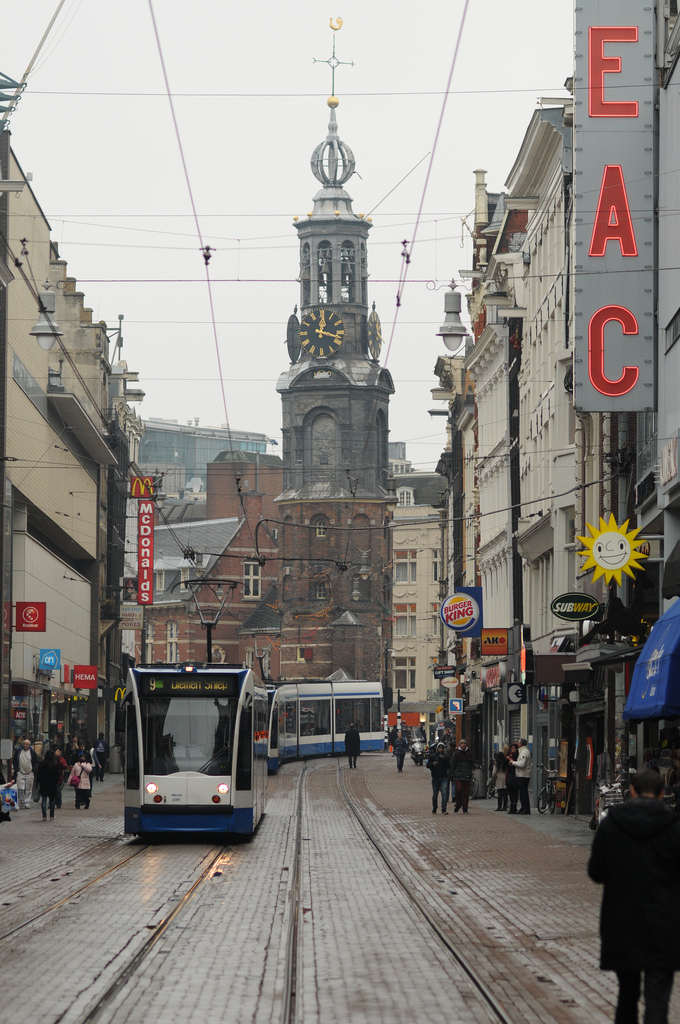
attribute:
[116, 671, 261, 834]
train — blue, white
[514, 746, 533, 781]
coat — white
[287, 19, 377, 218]
steeple — gold, silver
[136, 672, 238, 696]
board — digital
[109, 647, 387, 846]
train — blue, white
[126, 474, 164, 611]
sign — McDonald's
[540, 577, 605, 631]
sign — small, subway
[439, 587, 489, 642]
sign — Burger King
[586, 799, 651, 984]
jacket — black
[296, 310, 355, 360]
clock — large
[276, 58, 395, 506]
building — tall, clock tower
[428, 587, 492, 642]
sign — Burger King, blue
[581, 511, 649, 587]
sign — sun shaped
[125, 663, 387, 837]
train — blue, white, silver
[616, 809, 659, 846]
coat — black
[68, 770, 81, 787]
bag — pink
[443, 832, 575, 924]
walkway — brick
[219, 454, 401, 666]
building — red brick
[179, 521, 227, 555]
roof — shingled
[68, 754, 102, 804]
woman — pink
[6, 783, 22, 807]
bag — white, blue, plastic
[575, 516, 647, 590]
sign — Yellow 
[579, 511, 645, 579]
sun — smiling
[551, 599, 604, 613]
letters — yellow, white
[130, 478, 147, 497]
arches — golden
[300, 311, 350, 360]
clock — black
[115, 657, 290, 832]
street car — white, blue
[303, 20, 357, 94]
cross — grey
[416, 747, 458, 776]
jacket — thick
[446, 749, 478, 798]
jacket — thick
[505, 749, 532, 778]
jacket — thick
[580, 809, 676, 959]
jacket — thick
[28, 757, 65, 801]
jacket — thick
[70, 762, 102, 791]
jacket — thick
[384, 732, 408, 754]
jacket — thick